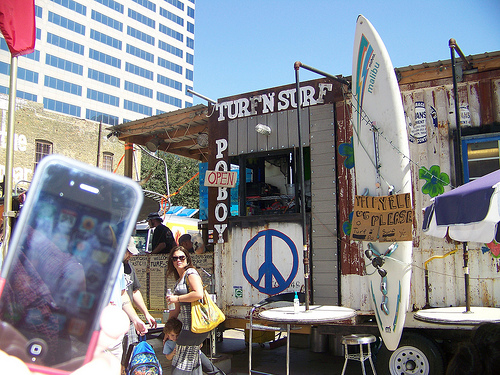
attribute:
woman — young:
[163, 245, 230, 375]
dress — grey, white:
[169, 269, 211, 374]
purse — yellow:
[181, 274, 228, 333]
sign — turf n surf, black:
[215, 80, 336, 126]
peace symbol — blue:
[240, 228, 298, 298]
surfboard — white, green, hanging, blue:
[347, 9, 416, 354]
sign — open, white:
[202, 166, 241, 189]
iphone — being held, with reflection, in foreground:
[0, 153, 145, 375]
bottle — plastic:
[164, 287, 178, 311]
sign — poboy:
[211, 133, 231, 247]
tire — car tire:
[370, 330, 447, 375]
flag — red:
[0, 1, 39, 61]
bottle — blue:
[291, 290, 301, 316]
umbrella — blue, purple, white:
[411, 166, 499, 249]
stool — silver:
[337, 328, 379, 375]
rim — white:
[385, 346, 430, 375]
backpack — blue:
[121, 332, 162, 374]